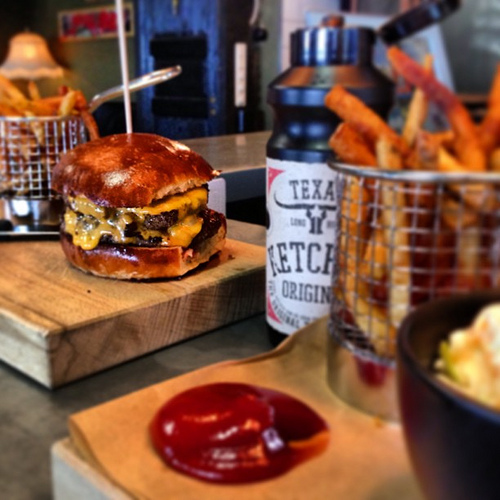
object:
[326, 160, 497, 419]
container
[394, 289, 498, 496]
bowl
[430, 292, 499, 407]
food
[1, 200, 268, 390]
board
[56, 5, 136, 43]
painting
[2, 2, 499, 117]
wall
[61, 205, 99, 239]
cheese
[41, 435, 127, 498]
brown board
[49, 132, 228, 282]
cheeseburger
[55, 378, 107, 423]
ground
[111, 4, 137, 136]
stick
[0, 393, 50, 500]
ground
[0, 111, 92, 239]
container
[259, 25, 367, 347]
bottle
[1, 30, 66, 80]
lampshade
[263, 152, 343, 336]
label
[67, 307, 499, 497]
bag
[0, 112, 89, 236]
basket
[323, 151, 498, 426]
basket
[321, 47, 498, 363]
french fries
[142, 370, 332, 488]
ketchup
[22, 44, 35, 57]
light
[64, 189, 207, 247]
eyecheese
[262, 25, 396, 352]
bottle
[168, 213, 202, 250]
cheese